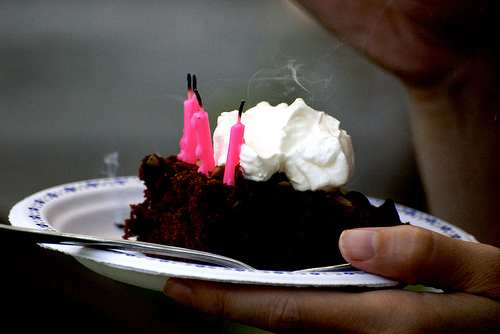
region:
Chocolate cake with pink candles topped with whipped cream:
[133, 70, 409, 265]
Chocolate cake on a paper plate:
[17, 142, 480, 294]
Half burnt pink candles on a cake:
[175, 71, 247, 188]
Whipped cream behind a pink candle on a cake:
[215, 97, 356, 194]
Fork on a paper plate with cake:
[2, 221, 355, 273]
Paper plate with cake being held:
[18, 173, 498, 331]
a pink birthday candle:
[224, 99, 245, 188]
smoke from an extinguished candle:
[240, 42, 332, 99]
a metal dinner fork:
[0, 222, 350, 274]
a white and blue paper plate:
[8, 174, 476, 295]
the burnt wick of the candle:
[235, 96, 245, 123]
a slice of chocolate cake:
[130, 184, 338, 270]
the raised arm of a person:
[393, 2, 498, 198]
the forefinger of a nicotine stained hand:
[163, 278, 410, 333]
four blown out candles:
[178, 74, 248, 183]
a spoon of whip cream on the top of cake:
[214, 96, 352, 188]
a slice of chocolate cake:
[117, 150, 407, 270]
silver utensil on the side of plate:
[1, 220, 349, 278]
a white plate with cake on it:
[9, 175, 474, 292]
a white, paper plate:
[8, 179, 476, 294]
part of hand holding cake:
[163, 225, 498, 332]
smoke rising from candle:
[240, 36, 350, 101]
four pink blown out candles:
[181, 72, 245, 183]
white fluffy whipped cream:
[211, 96, 352, 190]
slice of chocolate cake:
[126, 155, 403, 265]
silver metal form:
[2, 222, 349, 274]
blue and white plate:
[7, 175, 477, 290]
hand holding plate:
[8, 176, 499, 329]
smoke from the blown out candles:
[142, 26, 374, 185]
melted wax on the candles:
[172, 72, 239, 187]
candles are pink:
[177, 73, 246, 183]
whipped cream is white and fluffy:
[210, 93, 357, 196]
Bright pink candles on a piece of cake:
[172, 75, 244, 180]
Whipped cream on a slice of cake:
[210, 92, 356, 190]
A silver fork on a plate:
[1, 220, 352, 272]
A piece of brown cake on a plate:
[117, 152, 405, 267]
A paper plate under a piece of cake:
[8, 174, 484, 286]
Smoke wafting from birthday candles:
[235, 50, 327, 87]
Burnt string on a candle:
[231, 101, 244, 112]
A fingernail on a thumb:
[340, 226, 385, 261]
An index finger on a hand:
[161, 275, 497, 325]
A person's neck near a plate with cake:
[397, 86, 499, 248]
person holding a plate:
[0, 70, 499, 332]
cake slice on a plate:
[8, 65, 479, 294]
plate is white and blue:
[9, 170, 477, 296]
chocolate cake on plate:
[8, 72, 482, 297]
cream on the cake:
[271, 113, 340, 178]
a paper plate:
[68, 189, 118, 231]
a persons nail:
[337, 229, 376, 258]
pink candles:
[168, 89, 254, 179]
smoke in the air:
[276, 53, 314, 85]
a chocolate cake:
[176, 182, 276, 249]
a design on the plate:
[24, 197, 51, 231]